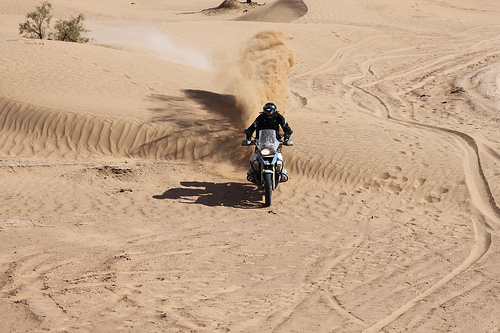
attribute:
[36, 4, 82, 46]
vegetation — green, small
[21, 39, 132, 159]
sand dune — small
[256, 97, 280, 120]
helmet — black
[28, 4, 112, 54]
trees — green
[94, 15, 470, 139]
desert — sandy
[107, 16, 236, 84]
smoke — white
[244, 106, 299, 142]
jacket — black, white